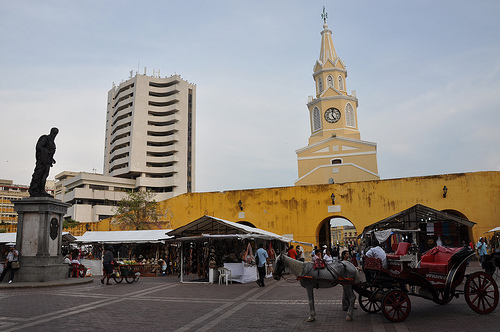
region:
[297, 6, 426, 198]
this is a large steeple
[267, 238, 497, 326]
a horse drawn carriage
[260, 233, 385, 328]
this is a horse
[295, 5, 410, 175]
the tower has a clock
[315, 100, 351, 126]
the clock reads 5:00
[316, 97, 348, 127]
the clock has a white face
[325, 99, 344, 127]
the hands of the clock are black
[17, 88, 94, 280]
a tall statue of a man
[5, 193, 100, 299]
the statue has a stone base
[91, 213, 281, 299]
this is a flea market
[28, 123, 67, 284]
a statue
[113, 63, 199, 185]
a tall white building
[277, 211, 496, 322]
a horse carriage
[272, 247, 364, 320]
a white horse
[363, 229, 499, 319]
a carriage with red seats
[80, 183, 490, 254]
a yellow wall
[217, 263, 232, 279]
a white chair under the tent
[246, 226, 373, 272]
people walking around a tent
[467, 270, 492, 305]
the wheel on the carriage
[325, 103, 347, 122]
a clock on the building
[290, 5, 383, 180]
a tall yellow clock tower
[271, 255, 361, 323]
a white horse all saddled up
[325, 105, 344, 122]
a black and white clock face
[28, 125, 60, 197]
a statue of a man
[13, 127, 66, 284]
a statue of a man on a tall pedestal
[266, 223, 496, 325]
a horse drawn carriage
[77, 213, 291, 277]
a long tent selling various goods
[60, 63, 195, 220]
a very tall building with curved windows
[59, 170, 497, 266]
a long yellow wall with archways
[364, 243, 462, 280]
a comfortable looking red seat in a carriage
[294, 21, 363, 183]
tan clock tower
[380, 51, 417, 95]
white clouds in blue sky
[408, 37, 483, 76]
white clouds in blue sky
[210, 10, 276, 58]
white clouds in blue sky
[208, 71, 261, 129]
white clouds in blue sky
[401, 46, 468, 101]
white clouds in blue sky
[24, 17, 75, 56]
white clouds in blue sky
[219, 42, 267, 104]
white clouds in blue sky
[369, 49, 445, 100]
white clouds in blue sky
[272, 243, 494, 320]
a horse and carriage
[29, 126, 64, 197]
a black statue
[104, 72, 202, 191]
a multi floored building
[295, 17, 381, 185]
a steeple with a clock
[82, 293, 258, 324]
a brick covering on the ground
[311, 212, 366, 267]
an archway in the wall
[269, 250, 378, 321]
a white and brown horse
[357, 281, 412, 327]
front wheels on the carriage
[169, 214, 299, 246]
a tin roof over some objects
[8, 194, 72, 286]
a podium for the statue to stand on